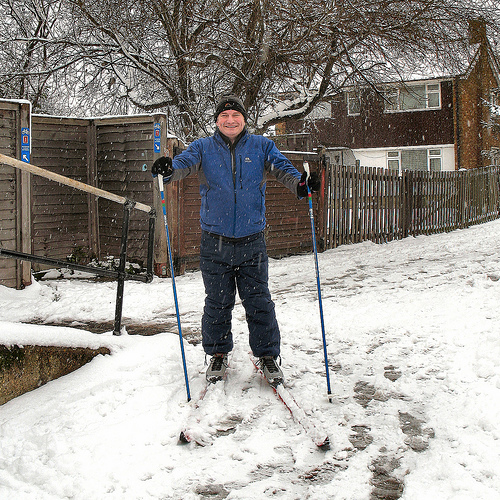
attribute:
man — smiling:
[150, 96, 319, 384]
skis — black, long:
[181, 383, 332, 449]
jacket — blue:
[167, 131, 304, 234]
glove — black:
[150, 156, 177, 179]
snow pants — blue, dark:
[197, 229, 283, 358]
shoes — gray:
[203, 353, 284, 384]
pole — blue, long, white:
[302, 160, 334, 407]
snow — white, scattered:
[1, 214, 500, 499]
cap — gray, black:
[214, 95, 250, 120]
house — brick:
[271, 16, 500, 205]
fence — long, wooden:
[325, 154, 500, 247]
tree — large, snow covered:
[71, 1, 497, 137]